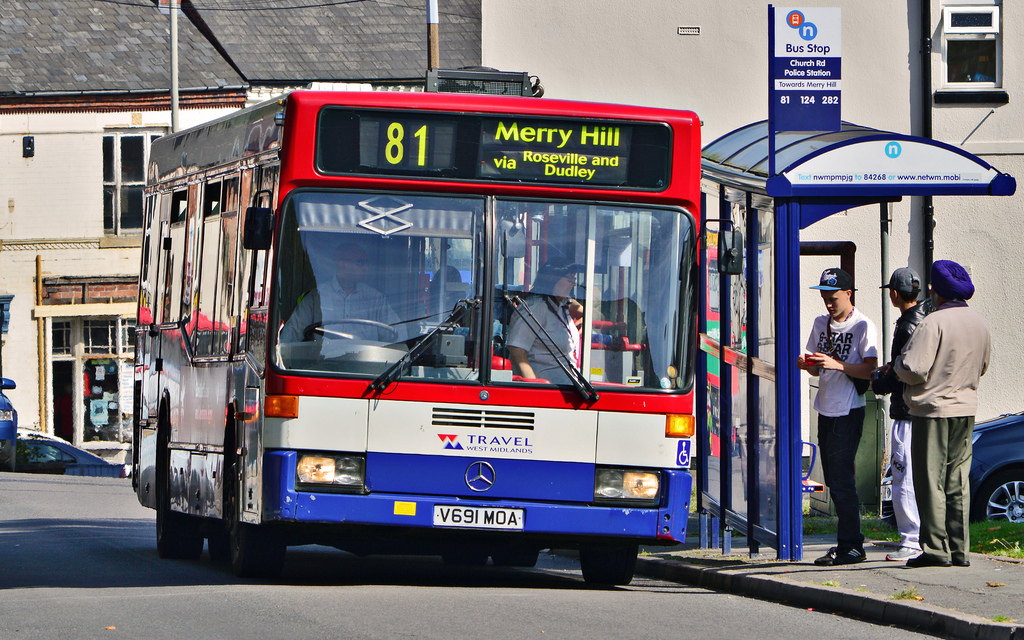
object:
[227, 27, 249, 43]
roof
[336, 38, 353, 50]
roof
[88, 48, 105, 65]
roof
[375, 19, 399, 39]
roof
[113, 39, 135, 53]
roof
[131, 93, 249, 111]
shingle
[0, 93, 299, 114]
shingle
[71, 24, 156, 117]
shingle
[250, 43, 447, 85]
shingle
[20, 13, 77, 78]
shingle